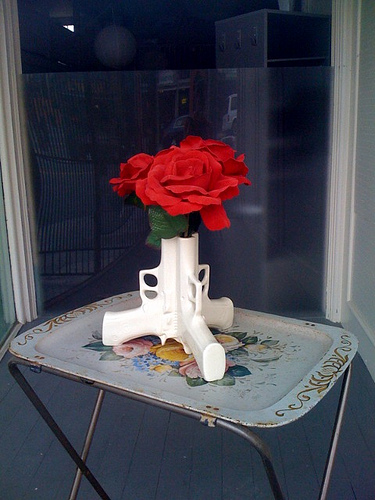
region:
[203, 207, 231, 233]
red petal on flower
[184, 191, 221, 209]
red petal on flower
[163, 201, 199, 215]
red petal on flower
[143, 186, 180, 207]
red petal on flower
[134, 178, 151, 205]
red petal on flower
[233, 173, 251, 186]
red petal on flower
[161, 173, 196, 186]
red petal on flower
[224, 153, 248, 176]
red petal on flower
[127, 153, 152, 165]
red petal on flower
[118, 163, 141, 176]
red petal on flower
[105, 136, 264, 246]
red flower in vase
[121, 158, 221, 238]
green leaves of flowers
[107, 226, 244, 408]
white guns for vase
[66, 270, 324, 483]
vase on white tray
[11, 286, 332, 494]
tray has grey legs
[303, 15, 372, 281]
white frame around window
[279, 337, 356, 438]
gold border on tray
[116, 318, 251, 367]
flower image on tray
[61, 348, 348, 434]
rust around edge of tray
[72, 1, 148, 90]
globe light in window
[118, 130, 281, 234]
A red rose petals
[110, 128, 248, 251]
Green leaves and Rose petals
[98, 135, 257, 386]
White ceramic stand with three legs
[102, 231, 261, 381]
Different design in the stand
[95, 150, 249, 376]
Rose is placed on the stand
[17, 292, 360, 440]
Iron stand with x type legs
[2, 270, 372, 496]
Design appears on either side of the stnad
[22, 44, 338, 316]
A glass window on the backside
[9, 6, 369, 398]
Shadow of other products appear in the window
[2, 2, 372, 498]
Blue wooden flooring with different woods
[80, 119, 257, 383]
flowers in gun vase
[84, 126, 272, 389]
flowers in unique gun vase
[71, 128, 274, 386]
flowers in different gun vase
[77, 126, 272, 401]
flowers in white gun vase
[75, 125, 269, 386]
flowers in special gun vase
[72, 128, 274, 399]
flowers in stylish gun vase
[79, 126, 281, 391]
red flowers in gun vase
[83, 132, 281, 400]
red flowers in nice gun vase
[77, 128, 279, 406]
red flowers in white gun vase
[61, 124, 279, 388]
red flowers in unique gun vase